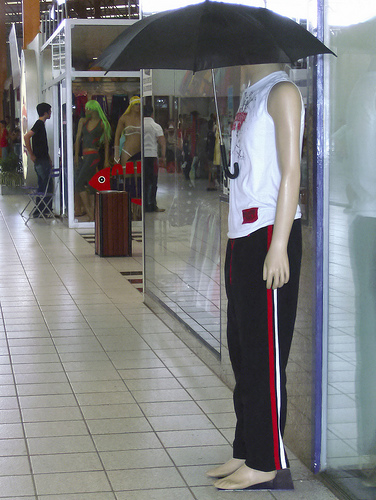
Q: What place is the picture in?
A: It is at the mall.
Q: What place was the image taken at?
A: It was taken at the mall.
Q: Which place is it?
A: It is a mall.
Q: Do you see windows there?
A: Yes, there is a window.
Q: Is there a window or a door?
A: Yes, there is a window.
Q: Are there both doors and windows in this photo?
A: No, there is a window but no doors.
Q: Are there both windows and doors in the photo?
A: No, there is a window but no doors.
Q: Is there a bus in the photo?
A: No, there are no buses.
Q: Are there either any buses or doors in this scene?
A: No, there are no buses or doors.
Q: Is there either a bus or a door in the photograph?
A: No, there are no buses or doors.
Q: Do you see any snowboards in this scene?
A: No, there are no snowboards.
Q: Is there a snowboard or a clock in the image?
A: No, there are no snowboards or clocks.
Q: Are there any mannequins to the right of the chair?
A: Yes, there is a mannequin to the right of the chair.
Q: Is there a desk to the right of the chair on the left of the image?
A: No, there is a mannequin to the right of the chair.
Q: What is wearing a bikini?
A: The mannequin is wearing a bikini.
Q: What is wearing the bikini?
A: The mannequin is wearing a bikini.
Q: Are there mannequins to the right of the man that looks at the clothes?
A: Yes, there is a mannequin to the right of the man.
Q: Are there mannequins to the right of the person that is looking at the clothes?
A: Yes, there is a mannequin to the right of the man.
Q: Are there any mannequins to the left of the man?
A: No, the mannequin is to the right of the man.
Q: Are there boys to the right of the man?
A: No, there is a mannequin to the right of the man.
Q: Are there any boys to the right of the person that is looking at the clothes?
A: No, there is a mannequin to the right of the man.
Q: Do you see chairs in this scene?
A: Yes, there is a chair.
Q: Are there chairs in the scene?
A: Yes, there is a chair.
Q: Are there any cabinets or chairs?
A: Yes, there is a chair.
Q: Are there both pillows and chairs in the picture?
A: No, there is a chair but no pillows.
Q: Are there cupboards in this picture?
A: No, there are no cupboards.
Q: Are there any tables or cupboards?
A: No, there are no cupboards or tables.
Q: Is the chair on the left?
A: Yes, the chair is on the left of the image.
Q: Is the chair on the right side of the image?
A: No, the chair is on the left of the image.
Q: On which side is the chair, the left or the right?
A: The chair is on the left of the image.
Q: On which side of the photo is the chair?
A: The chair is on the left of the image.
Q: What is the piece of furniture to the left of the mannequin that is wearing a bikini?
A: The piece of furniture is a chair.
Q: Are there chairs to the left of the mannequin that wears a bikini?
A: Yes, there is a chair to the left of the mannequin.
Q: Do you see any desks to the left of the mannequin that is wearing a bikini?
A: No, there is a chair to the left of the mannequin.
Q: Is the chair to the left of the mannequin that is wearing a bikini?
A: Yes, the chair is to the left of the mannequin.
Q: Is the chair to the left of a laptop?
A: No, the chair is to the left of the mannequin.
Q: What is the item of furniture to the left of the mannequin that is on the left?
A: The piece of furniture is a chair.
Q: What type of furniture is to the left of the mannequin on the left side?
A: The piece of furniture is a chair.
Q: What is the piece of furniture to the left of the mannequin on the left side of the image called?
A: The piece of furniture is a chair.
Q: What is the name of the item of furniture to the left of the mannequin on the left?
A: The piece of furniture is a chair.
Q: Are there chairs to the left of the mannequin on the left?
A: Yes, there is a chair to the left of the mannequin.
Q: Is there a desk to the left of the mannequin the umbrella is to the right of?
A: No, there is a chair to the left of the mannequin.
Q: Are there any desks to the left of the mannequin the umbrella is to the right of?
A: No, there is a chair to the left of the mannequin.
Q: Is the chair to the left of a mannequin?
A: Yes, the chair is to the left of a mannequin.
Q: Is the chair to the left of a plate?
A: No, the chair is to the left of a mannequin.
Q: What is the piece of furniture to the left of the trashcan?
A: The piece of furniture is a chair.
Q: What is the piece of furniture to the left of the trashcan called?
A: The piece of furniture is a chair.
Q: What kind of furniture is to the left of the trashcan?
A: The piece of furniture is a chair.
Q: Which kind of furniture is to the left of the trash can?
A: The piece of furniture is a chair.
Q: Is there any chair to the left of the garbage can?
A: Yes, there is a chair to the left of the garbage can.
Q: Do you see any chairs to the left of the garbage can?
A: Yes, there is a chair to the left of the garbage can.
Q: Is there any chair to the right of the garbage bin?
A: No, the chair is to the left of the garbage bin.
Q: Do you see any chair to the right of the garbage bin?
A: No, the chair is to the left of the garbage bin.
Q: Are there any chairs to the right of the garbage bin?
A: No, the chair is to the left of the garbage bin.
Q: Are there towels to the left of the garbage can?
A: No, there is a chair to the left of the garbage can.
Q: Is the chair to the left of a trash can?
A: Yes, the chair is to the left of a trash can.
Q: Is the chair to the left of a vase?
A: No, the chair is to the left of a trash can.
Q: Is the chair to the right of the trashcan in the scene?
A: No, the chair is to the left of the trashcan.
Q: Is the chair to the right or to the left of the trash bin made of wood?
A: The chair is to the left of the trash bin.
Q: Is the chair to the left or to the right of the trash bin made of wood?
A: The chair is to the left of the trash bin.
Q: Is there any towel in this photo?
A: No, there are no towels.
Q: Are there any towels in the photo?
A: No, there are no towels.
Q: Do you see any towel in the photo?
A: No, there are no towels.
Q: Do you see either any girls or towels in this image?
A: No, there are no towels or girls.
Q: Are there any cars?
A: No, there are no cars.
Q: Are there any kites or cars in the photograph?
A: No, there are no cars or kites.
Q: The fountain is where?
A: The fountain is in the mall.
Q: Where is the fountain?
A: The fountain is in the mall.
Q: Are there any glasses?
A: No, there are no glasses.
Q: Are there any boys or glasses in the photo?
A: No, there are no glasses or boys.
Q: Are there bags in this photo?
A: No, there are no bags.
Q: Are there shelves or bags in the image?
A: No, there are no bags or shelves.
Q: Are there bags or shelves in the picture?
A: No, there are no bags or shelves.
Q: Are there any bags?
A: No, there are no bags.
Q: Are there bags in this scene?
A: No, there are no bags.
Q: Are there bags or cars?
A: No, there are no bags or cars.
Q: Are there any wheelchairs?
A: No, there are no wheelchairs.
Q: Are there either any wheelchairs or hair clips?
A: No, there are no wheelchairs or hair clips.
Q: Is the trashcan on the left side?
A: Yes, the trashcan is on the left of the image.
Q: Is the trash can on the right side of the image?
A: No, the trash can is on the left of the image.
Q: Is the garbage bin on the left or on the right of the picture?
A: The garbage bin is on the left of the image.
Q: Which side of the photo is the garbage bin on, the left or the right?
A: The garbage bin is on the left of the image.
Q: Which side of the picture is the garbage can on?
A: The garbage can is on the left of the image.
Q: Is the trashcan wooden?
A: Yes, the trashcan is wooden.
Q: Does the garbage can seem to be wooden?
A: Yes, the garbage can is wooden.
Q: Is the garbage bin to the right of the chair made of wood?
A: Yes, the trashcan is made of wood.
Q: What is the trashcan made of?
A: The trashcan is made of wood.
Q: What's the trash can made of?
A: The trashcan is made of wood.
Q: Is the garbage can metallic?
A: No, the garbage can is wooden.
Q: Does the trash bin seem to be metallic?
A: No, the trash bin is wooden.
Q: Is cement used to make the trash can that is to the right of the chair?
A: No, the trashcan is made of wood.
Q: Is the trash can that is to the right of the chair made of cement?
A: No, the trashcan is made of wood.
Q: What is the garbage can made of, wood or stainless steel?
A: The garbage can is made of wood.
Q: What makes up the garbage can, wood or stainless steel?
A: The garbage can is made of wood.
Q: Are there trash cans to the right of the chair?
A: Yes, there is a trash can to the right of the chair.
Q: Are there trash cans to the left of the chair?
A: No, the trash can is to the right of the chair.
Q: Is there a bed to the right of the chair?
A: No, there is a trash can to the right of the chair.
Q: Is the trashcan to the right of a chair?
A: Yes, the trashcan is to the right of a chair.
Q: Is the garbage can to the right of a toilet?
A: No, the garbage can is to the right of a chair.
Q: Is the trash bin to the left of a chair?
A: No, the trash bin is to the right of a chair.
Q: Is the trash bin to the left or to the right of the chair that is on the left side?
A: The trash bin is to the right of the chair.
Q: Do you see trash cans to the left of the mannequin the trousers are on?
A: Yes, there is a trash can to the left of the mannequin.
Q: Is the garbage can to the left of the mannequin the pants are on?
A: Yes, the garbage can is to the left of the mannequin.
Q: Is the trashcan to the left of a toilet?
A: No, the trashcan is to the left of the mannequin.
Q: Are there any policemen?
A: No, there are no policemen.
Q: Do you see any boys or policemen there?
A: No, there are no policemen or boys.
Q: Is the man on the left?
A: Yes, the man is on the left of the image.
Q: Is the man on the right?
A: No, the man is on the left of the image.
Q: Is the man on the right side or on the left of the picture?
A: The man is on the left of the image.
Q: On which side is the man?
A: The man is on the left of the image.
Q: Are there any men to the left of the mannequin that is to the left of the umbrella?
A: Yes, there is a man to the left of the mannequin.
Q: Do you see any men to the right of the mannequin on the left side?
A: No, the man is to the left of the mannequin.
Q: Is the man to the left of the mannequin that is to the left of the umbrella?
A: Yes, the man is to the left of the mannequin.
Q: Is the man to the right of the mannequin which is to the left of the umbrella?
A: No, the man is to the left of the mannequin.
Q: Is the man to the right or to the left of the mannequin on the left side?
A: The man is to the left of the mannequin.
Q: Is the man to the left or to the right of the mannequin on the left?
A: The man is to the left of the mannequin.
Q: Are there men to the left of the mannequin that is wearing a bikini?
A: Yes, there is a man to the left of the mannequin.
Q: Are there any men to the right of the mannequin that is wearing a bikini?
A: No, the man is to the left of the mannequin.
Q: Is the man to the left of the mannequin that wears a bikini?
A: Yes, the man is to the left of the mannequin.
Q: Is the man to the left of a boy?
A: No, the man is to the left of the mannequin.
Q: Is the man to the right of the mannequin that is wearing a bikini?
A: No, the man is to the left of the mannequin.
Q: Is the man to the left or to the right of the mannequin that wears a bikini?
A: The man is to the left of the mannequin.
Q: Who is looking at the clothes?
A: The man is looking at the clothes.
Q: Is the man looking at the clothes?
A: Yes, the man is looking at the clothes.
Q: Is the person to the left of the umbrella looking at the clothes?
A: Yes, the man is looking at the clothes.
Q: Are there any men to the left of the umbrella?
A: Yes, there is a man to the left of the umbrella.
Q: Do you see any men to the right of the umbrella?
A: No, the man is to the left of the umbrella.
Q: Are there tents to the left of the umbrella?
A: No, there is a man to the left of the umbrella.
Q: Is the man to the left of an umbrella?
A: Yes, the man is to the left of an umbrella.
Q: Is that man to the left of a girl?
A: No, the man is to the left of an umbrella.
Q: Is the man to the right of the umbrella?
A: No, the man is to the left of the umbrella.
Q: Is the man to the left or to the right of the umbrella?
A: The man is to the left of the umbrella.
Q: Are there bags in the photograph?
A: No, there are no bags.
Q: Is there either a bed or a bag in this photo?
A: No, there are no bags or beds.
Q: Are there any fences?
A: No, there are no fences.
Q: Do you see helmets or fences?
A: No, there are no fences or helmets.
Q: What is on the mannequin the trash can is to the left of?
A: The trousers are on the mannequin.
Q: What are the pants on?
A: The pants are on the mannequin.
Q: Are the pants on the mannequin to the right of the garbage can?
A: Yes, the pants are on the mannequin.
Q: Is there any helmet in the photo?
A: No, there are no helmets.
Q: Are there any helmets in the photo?
A: No, there are no helmets.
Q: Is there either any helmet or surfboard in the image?
A: No, there are no helmets or surfboards.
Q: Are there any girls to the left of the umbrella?
A: No, there is a mannequin to the left of the umbrella.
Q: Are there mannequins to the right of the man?
A: Yes, there is a mannequin to the right of the man.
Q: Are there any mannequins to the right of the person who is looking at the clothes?
A: Yes, there is a mannequin to the right of the man.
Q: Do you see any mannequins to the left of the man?
A: No, the mannequin is to the right of the man.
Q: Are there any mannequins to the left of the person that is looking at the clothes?
A: No, the mannequin is to the right of the man.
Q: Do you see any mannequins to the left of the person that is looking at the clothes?
A: No, the mannequin is to the right of the man.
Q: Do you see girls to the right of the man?
A: No, there is a mannequin to the right of the man.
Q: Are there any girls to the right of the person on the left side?
A: No, there is a mannequin to the right of the man.